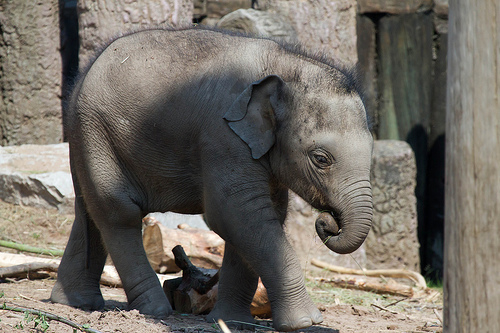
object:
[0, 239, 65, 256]
branch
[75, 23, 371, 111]
hair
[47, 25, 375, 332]
elephant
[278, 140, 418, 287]
block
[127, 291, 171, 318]
foot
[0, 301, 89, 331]
branch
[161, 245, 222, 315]
branches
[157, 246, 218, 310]
wood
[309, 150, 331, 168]
eye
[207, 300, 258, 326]
foot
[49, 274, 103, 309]
foot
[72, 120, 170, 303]
leg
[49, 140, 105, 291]
leg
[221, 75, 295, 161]
ear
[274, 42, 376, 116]
fur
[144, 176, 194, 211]
stomach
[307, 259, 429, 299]
stick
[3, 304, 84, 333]
leaf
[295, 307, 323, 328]
toe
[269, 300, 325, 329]
foot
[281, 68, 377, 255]
head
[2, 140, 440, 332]
ground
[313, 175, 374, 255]
trunk